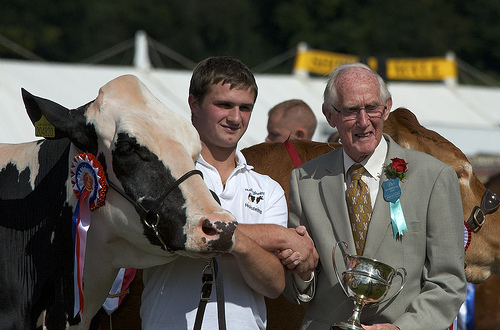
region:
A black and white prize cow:
[0, 70, 241, 328]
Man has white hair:
[310, 55, 396, 165]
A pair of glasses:
[321, 90, 391, 120]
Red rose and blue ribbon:
[376, 151, 412, 246]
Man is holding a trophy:
[285, 55, 471, 326]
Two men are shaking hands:
[135, 47, 470, 324]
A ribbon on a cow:
[51, 142, 111, 317]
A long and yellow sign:
[287, 32, 457, 89]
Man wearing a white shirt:
[136, 47, 286, 327]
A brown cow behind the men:
[237, 101, 497, 326]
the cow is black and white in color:
[5, 69, 233, 329]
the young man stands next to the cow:
[169, 42, 296, 327]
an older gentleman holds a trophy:
[296, 60, 471, 328]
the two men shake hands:
[266, 219, 330, 279]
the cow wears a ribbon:
[58, 145, 108, 327]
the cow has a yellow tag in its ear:
[28, 99, 64, 159]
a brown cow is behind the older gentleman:
[265, 100, 495, 282]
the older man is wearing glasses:
[323, 101, 401, 123]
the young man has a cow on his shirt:
[242, 185, 264, 217]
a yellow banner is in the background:
[286, 37, 461, 90]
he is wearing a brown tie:
[347, 165, 371, 247]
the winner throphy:
[331, 241, 403, 328]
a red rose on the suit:
[389, 157, 407, 179]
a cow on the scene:
[2, 74, 235, 326]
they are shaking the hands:
[256, 217, 331, 284]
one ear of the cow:
[21, 89, 93, 145]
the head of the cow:
[76, 75, 232, 257]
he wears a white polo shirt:
[146, 144, 285, 329]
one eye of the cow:
[112, 130, 148, 163]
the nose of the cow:
[197, 211, 239, 246]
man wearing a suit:
[281, 49, 476, 329]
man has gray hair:
[289, 54, 447, 223]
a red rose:
[383, 148, 410, 185]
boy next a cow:
[6, 36, 307, 326]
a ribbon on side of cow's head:
[55, 148, 115, 320]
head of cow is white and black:
[89, 67, 241, 277]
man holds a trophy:
[285, 55, 480, 326]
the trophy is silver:
[324, 235, 409, 327]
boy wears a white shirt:
[127, 45, 295, 329]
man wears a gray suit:
[276, 54, 475, 329]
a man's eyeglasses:
[333, 104, 390, 122]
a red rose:
[388, 155, 411, 170]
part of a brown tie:
[338, 170, 373, 253]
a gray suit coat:
[289, 135, 464, 329]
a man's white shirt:
[130, 151, 287, 328]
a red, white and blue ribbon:
[65, 147, 105, 316]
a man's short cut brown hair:
[187, 50, 256, 107]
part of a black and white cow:
[0, 71, 246, 328]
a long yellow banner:
[298, 48, 450, 82]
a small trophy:
[327, 240, 409, 329]